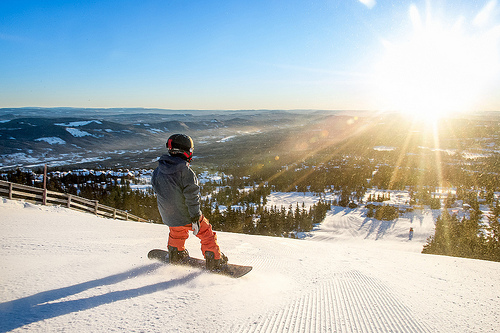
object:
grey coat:
[150, 154, 202, 227]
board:
[94, 200, 100, 216]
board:
[67, 193, 72, 208]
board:
[9, 183, 13, 200]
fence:
[0, 180, 148, 222]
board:
[113, 209, 117, 220]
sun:
[394, 48, 470, 125]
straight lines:
[223, 271, 439, 332]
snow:
[2, 277, 496, 331]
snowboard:
[148, 249, 253, 279]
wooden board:
[0, 182, 10, 193]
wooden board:
[12, 181, 42, 192]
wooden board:
[11, 190, 42, 200]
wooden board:
[98, 200, 115, 213]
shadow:
[0, 259, 204, 332]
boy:
[150, 134, 227, 274]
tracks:
[0, 237, 142, 258]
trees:
[367, 203, 399, 221]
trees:
[422, 209, 500, 262]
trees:
[222, 202, 313, 238]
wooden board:
[119, 212, 130, 222]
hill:
[5, 235, 419, 333]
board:
[43, 188, 48, 205]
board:
[47, 190, 68, 204]